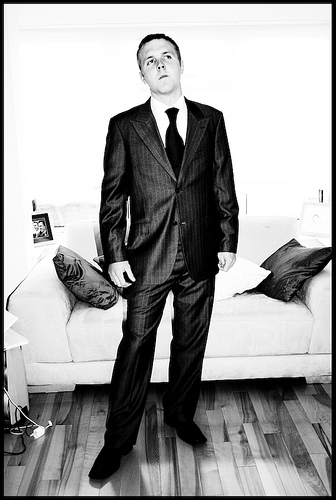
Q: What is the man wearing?
A: A suit.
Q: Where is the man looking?
A: Up and to the left.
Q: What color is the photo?
A: Black and white.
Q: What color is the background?
A: White.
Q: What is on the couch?
A: Pillows.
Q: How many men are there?
A: One.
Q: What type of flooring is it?
A: Hardwood.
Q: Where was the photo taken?
A: A living room.